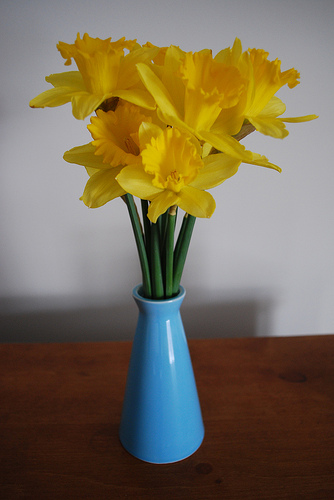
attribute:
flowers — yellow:
[39, 31, 297, 225]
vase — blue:
[117, 278, 206, 468]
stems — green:
[126, 209, 188, 299]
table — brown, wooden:
[25, 354, 309, 455]